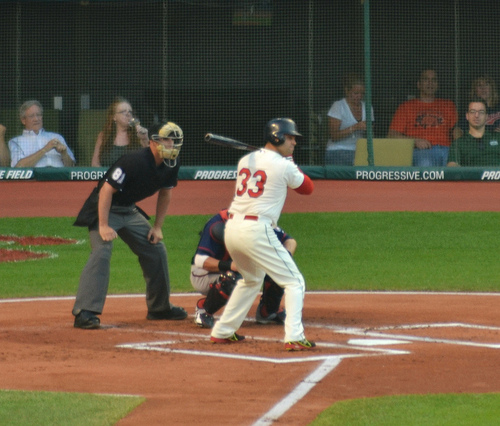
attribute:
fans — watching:
[0, 65, 499, 164]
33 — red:
[234, 164, 267, 199]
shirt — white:
[227, 145, 304, 221]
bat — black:
[202, 130, 261, 151]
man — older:
[9, 99, 77, 166]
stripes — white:
[2, 287, 497, 426]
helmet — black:
[263, 116, 303, 146]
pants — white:
[210, 215, 307, 342]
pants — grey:
[71, 206, 172, 316]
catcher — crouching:
[188, 207, 298, 329]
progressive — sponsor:
[192, 166, 243, 180]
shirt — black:
[100, 147, 178, 208]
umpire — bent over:
[71, 120, 187, 328]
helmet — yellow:
[147, 116, 183, 168]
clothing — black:
[73, 147, 178, 315]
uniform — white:
[208, 148, 314, 342]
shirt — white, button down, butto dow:
[7, 125, 76, 167]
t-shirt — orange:
[389, 96, 457, 146]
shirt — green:
[446, 127, 499, 169]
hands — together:
[42, 136, 67, 157]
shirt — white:
[323, 96, 376, 152]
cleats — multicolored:
[208, 332, 316, 354]